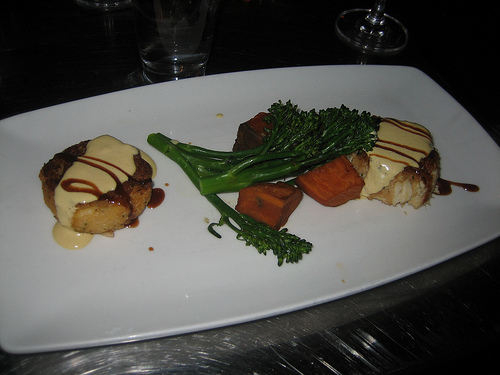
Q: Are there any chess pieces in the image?
A: No, there are no chess pieces.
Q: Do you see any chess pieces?
A: No, there are no chess pieces.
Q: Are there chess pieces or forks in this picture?
A: No, there are no chess pieces or forks.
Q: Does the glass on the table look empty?
A: Yes, the glass is empty.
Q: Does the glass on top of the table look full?
A: No, the glass is empty.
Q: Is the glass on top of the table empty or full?
A: The glass is empty.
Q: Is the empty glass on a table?
A: Yes, the glass is on a table.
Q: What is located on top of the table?
A: The glass is on top of the table.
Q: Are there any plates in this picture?
A: Yes, there is a plate.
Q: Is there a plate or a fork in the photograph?
A: Yes, there is a plate.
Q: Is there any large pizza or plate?
A: Yes, there is a large plate.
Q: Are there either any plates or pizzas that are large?
A: Yes, the plate is large.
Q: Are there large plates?
A: Yes, there is a large plate.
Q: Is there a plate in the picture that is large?
A: Yes, there is a plate that is large.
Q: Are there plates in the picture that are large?
A: Yes, there is a plate that is large.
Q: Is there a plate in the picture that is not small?
A: Yes, there is a large plate.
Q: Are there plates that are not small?
A: Yes, there is a large plate.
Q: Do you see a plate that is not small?
A: Yes, there is a large plate.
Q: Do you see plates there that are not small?
A: Yes, there is a large plate.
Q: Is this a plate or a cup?
A: This is a plate.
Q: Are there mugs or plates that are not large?
A: No, there is a plate but it is large.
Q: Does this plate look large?
A: Yes, the plate is large.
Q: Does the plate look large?
A: Yes, the plate is large.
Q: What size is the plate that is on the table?
A: The plate is large.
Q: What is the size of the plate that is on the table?
A: The plate is large.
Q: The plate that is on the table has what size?
A: The plate is large.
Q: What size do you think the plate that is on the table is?
A: The plate is large.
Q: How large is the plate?
A: The plate is large.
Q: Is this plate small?
A: No, the plate is large.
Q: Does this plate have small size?
A: No, the plate is large.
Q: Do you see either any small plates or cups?
A: No, there is a plate but it is large.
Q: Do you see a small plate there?
A: No, there is a plate but it is large.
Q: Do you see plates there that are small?
A: No, there is a plate but it is large.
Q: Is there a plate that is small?
A: No, there is a plate but it is large.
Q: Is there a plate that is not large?
A: No, there is a plate but it is large.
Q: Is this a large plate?
A: Yes, this is a large plate.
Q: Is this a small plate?
A: No, this is a large plate.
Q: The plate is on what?
A: The plate is on the table.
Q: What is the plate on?
A: The plate is on the table.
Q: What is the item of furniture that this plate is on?
A: The piece of furniture is a table.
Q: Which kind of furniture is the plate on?
A: The plate is on the table.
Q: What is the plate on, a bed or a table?
A: The plate is on a table.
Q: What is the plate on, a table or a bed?
A: The plate is on a table.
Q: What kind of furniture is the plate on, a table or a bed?
A: The plate is on a table.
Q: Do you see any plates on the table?
A: Yes, there is a plate on the table.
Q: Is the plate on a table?
A: Yes, the plate is on a table.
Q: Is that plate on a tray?
A: No, the plate is on a table.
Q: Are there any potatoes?
A: Yes, there is a potato.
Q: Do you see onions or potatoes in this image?
A: Yes, there is a potato.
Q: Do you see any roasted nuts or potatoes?
A: Yes, there is a roasted potato.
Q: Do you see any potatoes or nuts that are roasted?
A: Yes, the potato is roasted.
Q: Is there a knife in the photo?
A: No, there are no knives.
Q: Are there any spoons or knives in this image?
A: No, there are no knives or spoons.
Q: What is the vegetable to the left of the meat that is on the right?
A: The vegetable is a potato.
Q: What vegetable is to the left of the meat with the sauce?
A: The vegetable is a potato.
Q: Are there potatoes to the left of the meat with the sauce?
A: Yes, there is a potato to the left of the meat.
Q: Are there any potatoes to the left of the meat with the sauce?
A: Yes, there is a potato to the left of the meat.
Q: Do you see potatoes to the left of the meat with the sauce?
A: Yes, there is a potato to the left of the meat.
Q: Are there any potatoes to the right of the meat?
A: No, the potato is to the left of the meat.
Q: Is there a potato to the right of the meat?
A: No, the potato is to the left of the meat.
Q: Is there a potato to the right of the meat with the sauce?
A: No, the potato is to the left of the meat.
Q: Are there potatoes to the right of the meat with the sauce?
A: No, the potato is to the left of the meat.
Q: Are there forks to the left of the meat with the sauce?
A: No, there is a potato to the left of the meat.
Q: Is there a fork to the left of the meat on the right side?
A: No, there is a potato to the left of the meat.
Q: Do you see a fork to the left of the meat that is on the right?
A: No, there is a potato to the left of the meat.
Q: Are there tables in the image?
A: Yes, there is a table.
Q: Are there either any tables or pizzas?
A: Yes, there is a table.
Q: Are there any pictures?
A: No, there are no pictures.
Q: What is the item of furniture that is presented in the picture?
A: The piece of furniture is a table.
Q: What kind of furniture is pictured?
A: The furniture is a table.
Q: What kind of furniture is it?
A: The piece of furniture is a table.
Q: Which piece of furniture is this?
A: That is a table.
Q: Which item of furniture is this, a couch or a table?
A: That is a table.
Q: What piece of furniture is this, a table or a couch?
A: That is a table.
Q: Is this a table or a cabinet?
A: This is a table.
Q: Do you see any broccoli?
A: Yes, there is broccoli.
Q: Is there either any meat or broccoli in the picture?
A: Yes, there is broccoli.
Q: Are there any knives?
A: No, there are no knives.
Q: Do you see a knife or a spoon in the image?
A: No, there are no knives or spoons.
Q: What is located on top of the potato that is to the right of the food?
A: The broccoli is on top of the potato.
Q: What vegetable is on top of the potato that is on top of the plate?
A: The vegetable is broccoli.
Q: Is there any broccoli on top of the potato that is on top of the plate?
A: Yes, there is broccoli on top of the potato.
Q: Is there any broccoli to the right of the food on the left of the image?
A: Yes, there is broccoli to the right of the food.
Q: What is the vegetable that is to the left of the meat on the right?
A: The vegetable is broccoli.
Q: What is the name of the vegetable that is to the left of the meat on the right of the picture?
A: The vegetable is broccoli.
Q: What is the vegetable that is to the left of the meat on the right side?
A: The vegetable is broccoli.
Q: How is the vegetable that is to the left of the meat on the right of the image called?
A: The vegetable is broccoli.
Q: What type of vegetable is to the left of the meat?
A: The vegetable is broccoli.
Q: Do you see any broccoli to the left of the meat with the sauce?
A: Yes, there is broccoli to the left of the meat.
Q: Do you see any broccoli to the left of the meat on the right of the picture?
A: Yes, there is broccoli to the left of the meat.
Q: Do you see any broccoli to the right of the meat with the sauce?
A: No, the broccoli is to the left of the meat.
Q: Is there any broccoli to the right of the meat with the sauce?
A: No, the broccoli is to the left of the meat.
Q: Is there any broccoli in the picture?
A: Yes, there is broccoli.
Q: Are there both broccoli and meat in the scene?
A: Yes, there are both broccoli and meat.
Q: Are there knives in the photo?
A: No, there are no knives.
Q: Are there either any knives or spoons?
A: No, there are no knives or spoons.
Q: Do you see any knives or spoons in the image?
A: No, there are no knives or spoons.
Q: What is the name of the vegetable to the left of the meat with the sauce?
A: The vegetable is broccoli.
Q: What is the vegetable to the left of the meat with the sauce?
A: The vegetable is broccoli.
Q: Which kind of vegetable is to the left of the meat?
A: The vegetable is broccoli.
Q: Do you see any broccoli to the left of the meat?
A: Yes, there is broccoli to the left of the meat.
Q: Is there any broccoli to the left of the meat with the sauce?
A: Yes, there is broccoli to the left of the meat.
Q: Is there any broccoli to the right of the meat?
A: No, the broccoli is to the left of the meat.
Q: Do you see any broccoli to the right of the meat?
A: No, the broccoli is to the left of the meat.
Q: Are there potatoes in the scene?
A: Yes, there is a potato.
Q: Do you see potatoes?
A: Yes, there is a potato.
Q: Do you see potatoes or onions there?
A: Yes, there is a potato.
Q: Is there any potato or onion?
A: Yes, there is a potato.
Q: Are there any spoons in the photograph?
A: No, there are no spoons.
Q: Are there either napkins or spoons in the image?
A: No, there are no spoons or napkins.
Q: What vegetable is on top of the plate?
A: The vegetable is a potato.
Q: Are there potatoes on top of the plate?
A: Yes, there is a potato on top of the plate.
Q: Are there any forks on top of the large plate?
A: No, there is a potato on top of the plate.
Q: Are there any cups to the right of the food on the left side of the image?
A: No, there is a potato to the right of the food.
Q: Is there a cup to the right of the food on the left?
A: No, there is a potato to the right of the food.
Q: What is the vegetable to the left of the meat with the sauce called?
A: The vegetable is a potato.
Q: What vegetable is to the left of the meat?
A: The vegetable is a potato.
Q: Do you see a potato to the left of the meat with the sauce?
A: Yes, there is a potato to the left of the meat.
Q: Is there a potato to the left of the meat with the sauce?
A: Yes, there is a potato to the left of the meat.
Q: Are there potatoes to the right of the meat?
A: No, the potato is to the left of the meat.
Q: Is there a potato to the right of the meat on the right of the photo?
A: No, the potato is to the left of the meat.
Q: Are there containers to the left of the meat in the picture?
A: No, there is a potato to the left of the meat.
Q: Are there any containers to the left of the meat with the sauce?
A: No, there is a potato to the left of the meat.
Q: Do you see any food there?
A: Yes, there is food.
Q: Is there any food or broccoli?
A: Yes, there is food.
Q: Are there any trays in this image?
A: No, there are no trays.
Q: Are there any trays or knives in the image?
A: No, there are no trays or knives.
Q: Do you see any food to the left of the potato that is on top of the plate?
A: Yes, there is food to the left of the potato.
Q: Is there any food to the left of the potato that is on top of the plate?
A: Yes, there is food to the left of the potato.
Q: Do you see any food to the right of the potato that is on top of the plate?
A: No, the food is to the left of the potato.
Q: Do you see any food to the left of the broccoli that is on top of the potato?
A: Yes, there is food to the left of the broccoli.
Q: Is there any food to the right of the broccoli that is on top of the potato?
A: No, the food is to the left of the broccoli.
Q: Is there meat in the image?
A: Yes, there is meat.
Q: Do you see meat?
A: Yes, there is meat.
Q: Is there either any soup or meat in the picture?
A: Yes, there is meat.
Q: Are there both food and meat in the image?
A: Yes, there are both meat and food.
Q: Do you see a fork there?
A: No, there are no forks.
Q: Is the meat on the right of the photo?
A: Yes, the meat is on the right of the image.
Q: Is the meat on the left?
A: No, the meat is on the right of the image.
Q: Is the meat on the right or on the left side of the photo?
A: The meat is on the right of the image.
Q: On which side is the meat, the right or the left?
A: The meat is on the right of the image.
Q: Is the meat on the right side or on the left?
A: The meat is on the right of the image.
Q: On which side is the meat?
A: The meat is on the right of the image.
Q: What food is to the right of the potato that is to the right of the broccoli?
A: The food is meat.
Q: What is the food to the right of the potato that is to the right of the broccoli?
A: The food is meat.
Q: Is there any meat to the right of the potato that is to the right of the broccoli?
A: Yes, there is meat to the right of the potato.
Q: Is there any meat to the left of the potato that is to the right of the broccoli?
A: No, the meat is to the right of the potato.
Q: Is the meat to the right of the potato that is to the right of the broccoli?
A: Yes, the meat is to the right of the potato.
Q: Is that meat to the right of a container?
A: No, the meat is to the right of the potato.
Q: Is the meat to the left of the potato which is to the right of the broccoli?
A: No, the meat is to the right of the potato.